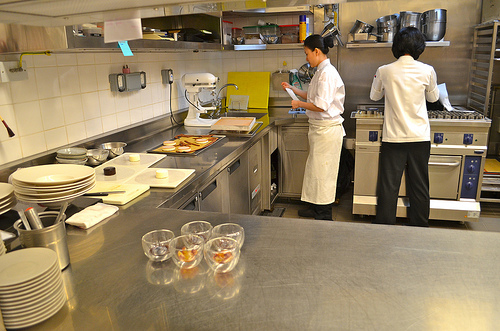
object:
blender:
[182, 73, 219, 127]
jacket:
[369, 56, 440, 144]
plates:
[10, 162, 96, 185]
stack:
[0, 247, 69, 331]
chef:
[370, 26, 440, 227]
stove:
[351, 103, 492, 224]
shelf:
[345, 41, 451, 50]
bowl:
[420, 8, 448, 21]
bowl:
[421, 23, 447, 41]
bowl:
[378, 32, 396, 42]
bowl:
[375, 14, 399, 27]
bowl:
[350, 19, 374, 33]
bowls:
[142, 220, 247, 274]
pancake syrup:
[179, 245, 198, 263]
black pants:
[375, 140, 430, 226]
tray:
[146, 134, 227, 156]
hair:
[391, 26, 426, 60]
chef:
[281, 34, 347, 221]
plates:
[0, 247, 58, 287]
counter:
[0, 119, 500, 330]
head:
[303, 34, 335, 68]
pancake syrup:
[214, 250, 234, 264]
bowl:
[141, 228, 175, 262]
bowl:
[168, 235, 204, 269]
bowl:
[212, 222, 245, 250]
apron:
[300, 120, 343, 205]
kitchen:
[0, 0, 497, 329]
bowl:
[180, 220, 213, 243]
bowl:
[204, 237, 245, 273]